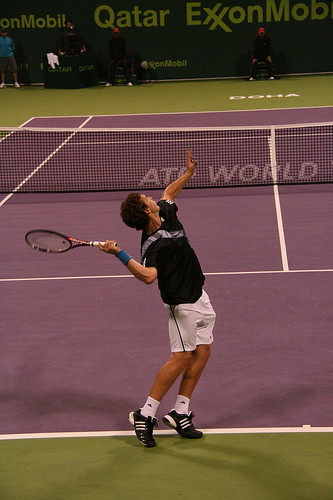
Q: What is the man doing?
A: Playing tennis.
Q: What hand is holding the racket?
A: The right.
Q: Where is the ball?
A: In the air.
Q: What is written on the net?
A: ATP WORLD.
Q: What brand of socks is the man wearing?
A: Adidas.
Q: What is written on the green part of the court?
A: DOHA.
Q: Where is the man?
A: In the court.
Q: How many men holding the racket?
A: One.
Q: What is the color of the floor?
A: Purple and green.